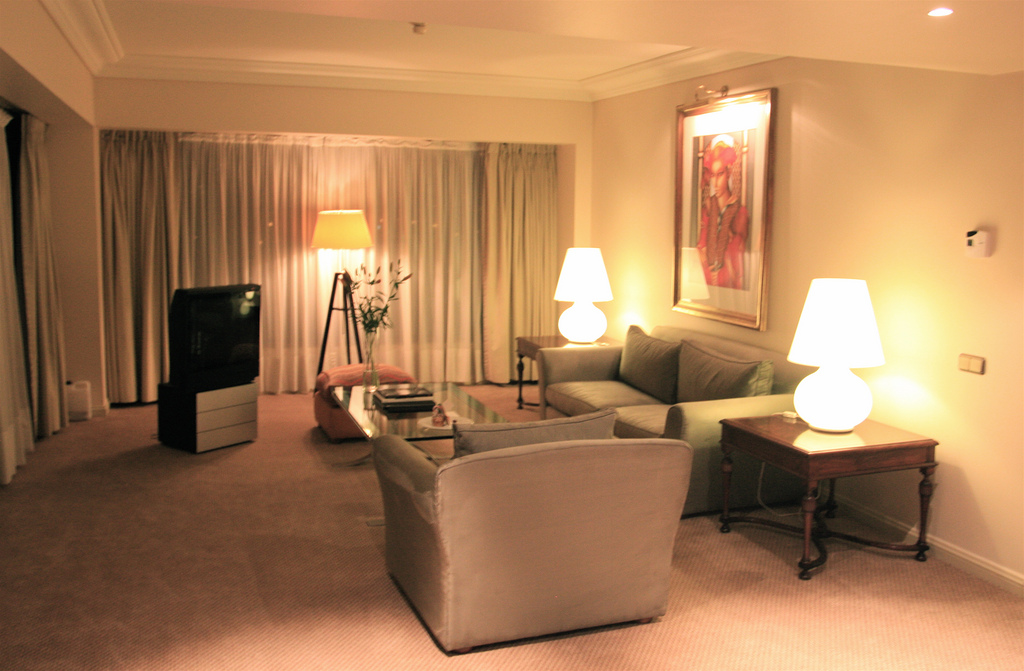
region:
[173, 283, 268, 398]
tv set is switched off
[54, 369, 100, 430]
The plastic jug on the floor behind the TV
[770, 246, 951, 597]
A lamp on a side table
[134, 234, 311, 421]
A black television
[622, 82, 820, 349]
Painting hanging on the wall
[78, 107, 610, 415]
Curtains are closed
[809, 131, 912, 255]
The wall is white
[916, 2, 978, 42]
Ceiling light turned on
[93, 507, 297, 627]
A beige carpet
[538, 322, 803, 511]
A couch against the wall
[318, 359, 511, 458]
A glass coffee table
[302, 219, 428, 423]
Flowers on the coffee table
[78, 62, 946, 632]
a empty family room at night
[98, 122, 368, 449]
lamp and television in front of a window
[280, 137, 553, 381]
Tall window with curtains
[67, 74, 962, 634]
A family room at night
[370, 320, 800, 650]
grey living room couch set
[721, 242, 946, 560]
lamp on an end table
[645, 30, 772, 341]
illuminated picture on a wall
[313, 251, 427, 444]
vase with plants on a coffee table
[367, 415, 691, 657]
grey armchair in a living room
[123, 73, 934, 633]
clean living room with the lights on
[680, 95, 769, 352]
a large red painting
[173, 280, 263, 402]
a black television on a stand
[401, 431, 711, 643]
a small love seat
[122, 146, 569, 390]
a set of large window curtains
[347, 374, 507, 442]
a glass coffee table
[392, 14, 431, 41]
a small sprinkler system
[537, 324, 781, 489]
a large couch against a wall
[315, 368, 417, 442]
a small cushion on the ground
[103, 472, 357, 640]
a living room carpet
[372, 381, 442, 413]
a black box sitting on a table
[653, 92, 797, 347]
Large painting hanging on the wall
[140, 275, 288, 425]
A black television is turned off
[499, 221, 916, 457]
Two matching lamps on side tables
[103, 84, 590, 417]
The curtains are closed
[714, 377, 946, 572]
A brown side table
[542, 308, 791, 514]
A gray couch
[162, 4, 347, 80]
The ceiling is white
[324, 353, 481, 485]
Items are on the coffee table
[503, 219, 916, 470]
Two matching lamps are turned on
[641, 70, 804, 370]
A large painting hanging on the wall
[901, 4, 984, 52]
Light in the ceiling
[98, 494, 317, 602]
The carpet is beige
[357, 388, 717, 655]
A gray couch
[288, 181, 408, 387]
A lamp near the window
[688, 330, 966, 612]
A side table next to the couch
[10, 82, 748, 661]
Predominantly, beige living room.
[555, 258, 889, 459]
Twin globe-style lamps, both lit, with traditional shades.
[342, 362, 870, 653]
Stuffed, couch and chair, beige.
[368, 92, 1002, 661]
Walls and and wall-to-wall carpeting, pale, terra-cotta color.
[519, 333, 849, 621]
Pair of dark wood end-tables, either end of couch.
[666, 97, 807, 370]
Very large portrait, only artwork on wall.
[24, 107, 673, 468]
Large, recessed windows with floor-ceiling drapes, closed.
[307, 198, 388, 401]
Lamp on tall pedestal.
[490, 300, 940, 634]
Curved, X-shaped, design element on bottom of tables.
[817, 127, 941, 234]
Wall is white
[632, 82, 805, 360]
Big painting on the wall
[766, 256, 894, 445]
A lamp is glowing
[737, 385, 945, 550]
A side table is brown